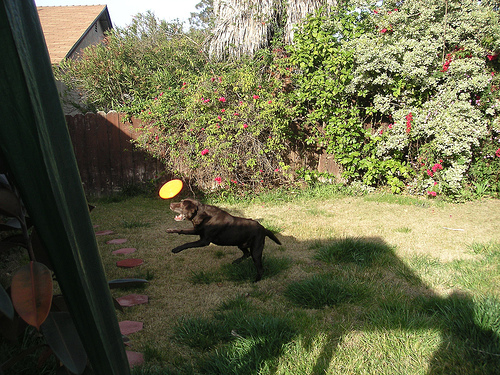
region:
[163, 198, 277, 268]
the dog is black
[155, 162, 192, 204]
the Frisbee is yellow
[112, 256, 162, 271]
the steeping stone is red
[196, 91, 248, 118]
the flowers on the bush are pink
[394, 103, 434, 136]
the flowers on the bush is reddish pink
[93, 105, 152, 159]
the fence is brown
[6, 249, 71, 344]
the leaf is orange and green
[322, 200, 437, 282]
the grass is light and dark in places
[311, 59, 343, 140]
the leaves on the bush are green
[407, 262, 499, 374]
the shadow is of a person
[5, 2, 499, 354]
a scene happening during the day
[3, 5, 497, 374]
a scene outside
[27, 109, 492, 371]
place in someone's backyard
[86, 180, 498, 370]
a green yard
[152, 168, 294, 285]
a black dog grabbing a yellow frisbee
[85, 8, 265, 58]
the sky with white clouds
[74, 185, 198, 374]
some stepping stones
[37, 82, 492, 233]
a brown fence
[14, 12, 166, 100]
a building in background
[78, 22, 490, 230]
some green bushes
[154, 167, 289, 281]
Dog is playing in the yard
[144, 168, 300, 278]
The dog is black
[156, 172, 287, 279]
The dog is big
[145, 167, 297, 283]
The dog is about to catch a frisbee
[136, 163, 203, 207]
The frisbee is yellow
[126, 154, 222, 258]
The frisbee is in the air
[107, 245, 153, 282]
The frisbee is on the ground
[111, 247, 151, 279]
The frisbee is red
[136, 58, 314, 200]
The Bottle Brush is in bloom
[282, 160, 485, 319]
The yard has a dead spot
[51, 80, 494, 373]
a scene in the backyard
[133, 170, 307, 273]
a black dog grabbing a Frisbee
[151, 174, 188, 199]
a yellow Frisbee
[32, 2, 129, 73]
another house in the background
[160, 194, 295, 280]
a large black dog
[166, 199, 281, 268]
a large black dog jumping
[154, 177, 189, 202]
a yellow frisbee in flight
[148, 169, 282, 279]
a dog chasing yellow frisbee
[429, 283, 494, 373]
a shadow of a person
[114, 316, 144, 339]
a concrete stepping stone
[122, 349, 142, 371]
a concrete stepping stone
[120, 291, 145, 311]
a concrete stepping stone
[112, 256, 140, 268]
a concrete stepping stone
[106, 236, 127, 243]
a concrete stepping stone